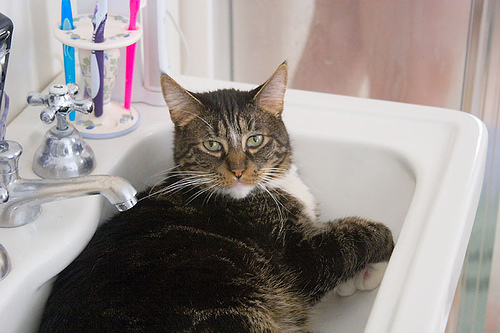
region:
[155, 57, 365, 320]
"A cat is pictured here"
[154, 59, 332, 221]
"The cat is looking at the camera"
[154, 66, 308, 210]
"The cat has green eyes"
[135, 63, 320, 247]
"The cat has long, white whiskers"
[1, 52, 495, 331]
"A cat is laying in the bathroom sink"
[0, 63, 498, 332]
"The sink is white"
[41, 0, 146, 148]
"Three tooth brushes"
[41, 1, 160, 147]
"One of the tooth brushes are pink"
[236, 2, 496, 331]
"Human legs can be seen behind the shower curtain"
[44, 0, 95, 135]
"This tooth brush is blue"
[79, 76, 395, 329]
a cat in the sink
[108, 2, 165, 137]
the toothbrush is pink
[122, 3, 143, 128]
the toothbrush is pink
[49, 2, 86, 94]
the toothbrush is blue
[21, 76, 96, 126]
The top portion of a faucet switch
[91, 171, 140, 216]
The front edge of a faucet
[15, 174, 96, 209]
The long portion of a faucet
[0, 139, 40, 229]
The body portion of a faucet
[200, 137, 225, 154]
The green right eye of the cat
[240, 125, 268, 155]
The green left eye of the cat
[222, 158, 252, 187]
The front nose of a cat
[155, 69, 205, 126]
The big right ear of a cat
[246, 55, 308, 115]
The big left ear of a cat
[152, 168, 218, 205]
The right side of the cat's whiskers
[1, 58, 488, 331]
white ceramic bathroom sink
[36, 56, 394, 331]
brown, tan and white tabby cat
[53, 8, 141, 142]
white patterned tooth brush holder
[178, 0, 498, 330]
glass shower doors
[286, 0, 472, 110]
person standing in the shower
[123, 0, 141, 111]
bright pink toothbrush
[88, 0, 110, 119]
dark purple and white toothbrush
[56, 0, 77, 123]
bright blue toothbrush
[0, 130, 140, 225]
silver metal water faucet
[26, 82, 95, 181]
silver water faucet handle next to the toothbrush holder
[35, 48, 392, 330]
Large dark cat in sink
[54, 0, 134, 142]
White toothbrush holder with green leaves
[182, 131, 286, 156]
Two green eyes of cat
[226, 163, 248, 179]
Very cute pink nose of cat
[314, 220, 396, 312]
Cat's front folded over next to each other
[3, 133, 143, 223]
Silver sink faucet with stopper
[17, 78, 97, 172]
Silver sink water handle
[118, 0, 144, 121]
Bright pink toothbrush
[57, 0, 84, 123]
Turquoise blue toothbrush in holder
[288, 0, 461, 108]
Person's legs who is showering